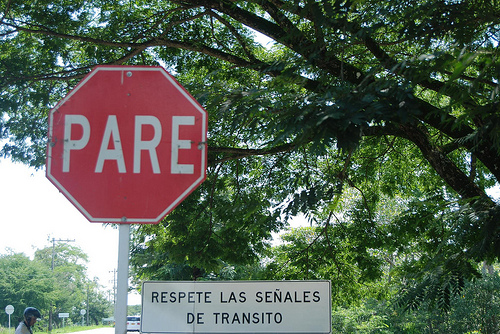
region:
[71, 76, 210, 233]
Red sign attached to pole.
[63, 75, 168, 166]
White writing on red sign.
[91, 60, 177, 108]
White line around edge of sign.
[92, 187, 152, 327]
Sign is attached to white pole.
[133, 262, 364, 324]
White next to red sign.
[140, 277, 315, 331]
Black writing on white sign.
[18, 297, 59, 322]
Person wearing dark helmet.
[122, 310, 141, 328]
White car driving on road.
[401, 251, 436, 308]
Green leaves on trees.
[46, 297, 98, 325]
Street signs on side of the road.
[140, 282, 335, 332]
A white sign with black lettering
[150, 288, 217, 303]
a word inscribed in black letters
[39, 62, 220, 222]
A red octagonal sign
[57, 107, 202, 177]
Capital letters written in white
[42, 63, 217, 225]
Octagonal sign with white borders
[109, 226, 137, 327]
A metal pole holding a sign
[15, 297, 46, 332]
The head of a man wearing a hat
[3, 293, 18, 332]
A sign in the distance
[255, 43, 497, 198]
A tree with green lush leaves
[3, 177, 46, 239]
a bright white shiny sky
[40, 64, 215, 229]
red and white stop sign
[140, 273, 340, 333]
white traffic sign with black letters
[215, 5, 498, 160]
trees covered in green leaves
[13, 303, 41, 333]
man walking across road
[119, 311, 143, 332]
white vehicle driving on road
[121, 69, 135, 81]
metal bolt securing stop sign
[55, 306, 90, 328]
white metal signs beside road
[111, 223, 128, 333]
white metal sign pole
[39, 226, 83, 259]
brown wooden electric pole beside road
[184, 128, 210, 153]
dirt on front of stop sign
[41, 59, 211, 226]
Sign is the shape of an octagon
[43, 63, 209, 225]
Sign is red with white letters and white frame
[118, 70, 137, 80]
Sign has silver bolt at top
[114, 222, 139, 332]
Sign post is gray and metal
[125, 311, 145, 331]
White automobile is driving down the road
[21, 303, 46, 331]
Man is wearing a black motorcycle helmet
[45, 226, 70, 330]
Tall wooden utility pole can be seen on left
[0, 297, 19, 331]
Back side of traffic sign on left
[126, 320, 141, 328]
White automobile has red tail lights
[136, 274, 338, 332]
Sign is white, rectangular, and has black lettering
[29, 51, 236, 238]
Red sign with white lettering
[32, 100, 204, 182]
The sign says PARE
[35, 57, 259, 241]
The red sign is an octagon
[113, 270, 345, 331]
White sign with black lettering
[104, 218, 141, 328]
White sign post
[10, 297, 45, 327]
A person wearing a helmet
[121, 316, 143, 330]
A white vehicle on the road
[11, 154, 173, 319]
The sky is bright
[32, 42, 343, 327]
The signs are in spanish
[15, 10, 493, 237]
Tree branches hanging over the road